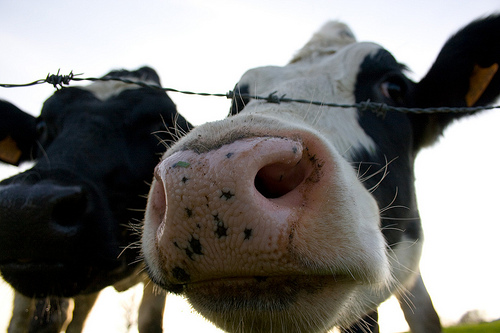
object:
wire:
[0, 78, 500, 114]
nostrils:
[247, 158, 308, 204]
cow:
[136, 1, 493, 330]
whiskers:
[344, 151, 408, 224]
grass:
[426, 320, 499, 331]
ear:
[411, 13, 499, 147]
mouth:
[153, 241, 358, 303]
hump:
[290, 18, 357, 67]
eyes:
[224, 83, 247, 114]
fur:
[374, 133, 413, 207]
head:
[135, 15, 499, 333]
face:
[141, 38, 423, 333]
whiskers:
[194, 300, 368, 333]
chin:
[164, 276, 367, 333]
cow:
[1, 60, 187, 306]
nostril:
[44, 194, 91, 230]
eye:
[378, 70, 410, 114]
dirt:
[302, 146, 330, 195]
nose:
[2, 181, 92, 265]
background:
[0, 0, 500, 333]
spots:
[208, 217, 230, 239]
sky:
[0, 0, 500, 333]